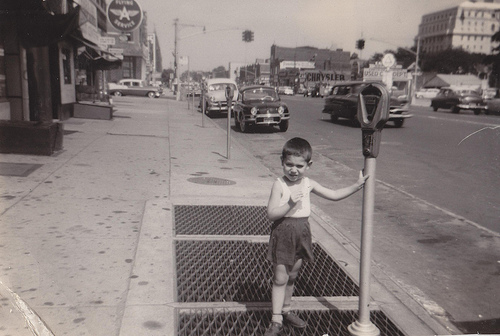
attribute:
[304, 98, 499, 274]
paved street — city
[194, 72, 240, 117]
car — white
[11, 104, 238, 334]
sidewalk — paved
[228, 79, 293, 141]
car — vintage , black 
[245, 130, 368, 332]
child — young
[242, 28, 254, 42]
traffic signal — electric 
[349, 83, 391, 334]
parking meter — vintage